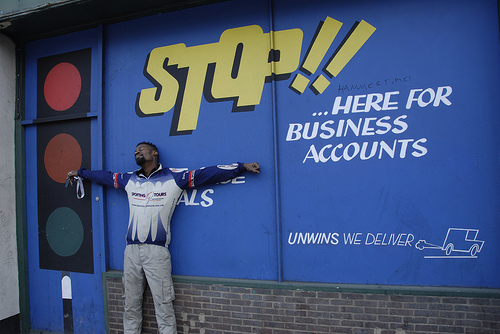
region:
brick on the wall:
[306, 303, 325, 313]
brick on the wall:
[342, 306, 364, 316]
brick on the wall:
[247, 317, 262, 324]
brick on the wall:
[399, 314, 427, 324]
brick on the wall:
[331, 320, 348, 330]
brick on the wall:
[207, 317, 232, 328]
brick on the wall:
[273, 313, 297, 322]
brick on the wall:
[318, 318, 343, 329]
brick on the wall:
[451, 317, 476, 325]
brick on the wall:
[362, 307, 392, 315]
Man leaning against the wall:
[58, 145, 241, 315]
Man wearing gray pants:
[105, 228, 172, 328]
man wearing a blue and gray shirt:
[82, 161, 217, 224]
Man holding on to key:
[62, 175, 89, 202]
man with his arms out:
[55, 148, 272, 200]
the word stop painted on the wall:
[123, 35, 401, 122]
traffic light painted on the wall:
[26, 47, 101, 282]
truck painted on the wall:
[431, 217, 488, 271]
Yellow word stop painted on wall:
[130, 28, 375, 108]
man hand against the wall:
[236, 153, 268, 184]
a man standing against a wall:
[55, 124, 270, 331]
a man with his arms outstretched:
[64, 136, 273, 332]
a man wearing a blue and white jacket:
[62, 135, 259, 249]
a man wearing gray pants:
[116, 229, 183, 332]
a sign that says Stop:
[135, 11, 309, 136]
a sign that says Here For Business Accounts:
[280, 83, 449, 174]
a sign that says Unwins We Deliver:
[284, 225, 414, 252]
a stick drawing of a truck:
[413, 220, 485, 263]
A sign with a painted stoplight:
[28, 43, 107, 328]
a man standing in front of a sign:
[52, 123, 281, 333]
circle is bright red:
[42, 60, 82, 111]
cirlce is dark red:
[44, 133, 81, 183]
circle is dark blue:
[44, 207, 82, 256]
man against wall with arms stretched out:
[65, 141, 262, 331]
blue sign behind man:
[108, 12, 497, 289]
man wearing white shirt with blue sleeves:
[67, 142, 267, 329]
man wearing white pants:
[69, 139, 262, 331]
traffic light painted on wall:
[37, 51, 96, 331]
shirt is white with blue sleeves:
[81, 163, 243, 247]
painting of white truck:
[413, 225, 485, 262]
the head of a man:
[121, 135, 176, 176]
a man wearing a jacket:
[19, 98, 310, 240]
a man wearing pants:
[117, 239, 249, 325]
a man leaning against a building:
[70, 115, 315, 286]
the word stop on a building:
[141, 2, 393, 143]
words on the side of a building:
[253, 51, 483, 268]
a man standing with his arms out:
[48, 137, 237, 324]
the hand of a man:
[44, 163, 98, 223]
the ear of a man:
[149, 142, 162, 160]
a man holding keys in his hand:
[53, 153, 128, 198]